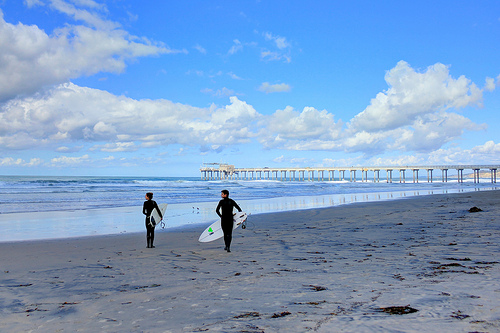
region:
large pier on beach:
[197, 157, 499, 192]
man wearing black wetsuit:
[212, 183, 242, 244]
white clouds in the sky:
[3, 72, 492, 159]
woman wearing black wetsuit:
[133, 187, 167, 234]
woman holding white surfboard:
[148, 203, 175, 225]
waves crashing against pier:
[138, 176, 345, 196]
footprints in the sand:
[111, 288, 198, 332]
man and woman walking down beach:
[128, 184, 255, 258]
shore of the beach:
[0, 214, 130, 246]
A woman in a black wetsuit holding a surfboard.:
[140, 191, 164, 248]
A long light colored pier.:
[200, 161, 498, 183]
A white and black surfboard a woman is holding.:
[147, 200, 167, 225]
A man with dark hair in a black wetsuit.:
[215, 189, 242, 251]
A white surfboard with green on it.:
[196, 208, 248, 242]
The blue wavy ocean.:
[1, 173, 499, 211]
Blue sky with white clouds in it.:
[0, 1, 499, 165]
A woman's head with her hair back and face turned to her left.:
[143, 191, 153, 199]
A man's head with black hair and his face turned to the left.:
[219, 188, 229, 198]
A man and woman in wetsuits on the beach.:
[141, 189, 243, 252]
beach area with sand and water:
[1, 168, 488, 314]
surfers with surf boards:
[136, 186, 250, 248]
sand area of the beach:
[3, 223, 483, 288]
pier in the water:
[191, 155, 498, 194]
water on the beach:
[12, 168, 289, 211]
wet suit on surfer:
[216, 198, 236, 235]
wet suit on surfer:
[132, 200, 162, 235]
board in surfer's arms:
[148, 202, 169, 228]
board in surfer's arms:
[202, 213, 257, 238]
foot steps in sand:
[111, 245, 237, 266]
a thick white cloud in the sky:
[365, 61, 467, 137]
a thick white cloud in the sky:
[208, 98, 333, 148]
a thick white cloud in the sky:
[15, 22, 123, 74]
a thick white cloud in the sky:
[24, 88, 149, 143]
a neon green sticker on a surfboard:
[204, 227, 211, 237]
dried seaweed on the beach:
[374, 294, 416, 319]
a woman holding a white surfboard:
[130, 187, 179, 254]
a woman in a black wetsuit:
[134, 187, 176, 257]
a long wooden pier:
[198, 152, 491, 175]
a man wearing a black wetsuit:
[207, 185, 233, 250]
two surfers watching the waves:
[140, 191, 247, 253]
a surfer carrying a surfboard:
[199, 188, 246, 252]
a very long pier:
[198, 160, 498, 185]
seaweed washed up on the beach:
[368, 303, 418, 319]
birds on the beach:
[190, 200, 198, 210]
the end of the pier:
[202, 160, 242, 183]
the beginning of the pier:
[456, 158, 496, 184]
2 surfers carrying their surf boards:
[140, 191, 245, 252]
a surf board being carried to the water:
[197, 211, 245, 243]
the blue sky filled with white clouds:
[2, 0, 492, 162]